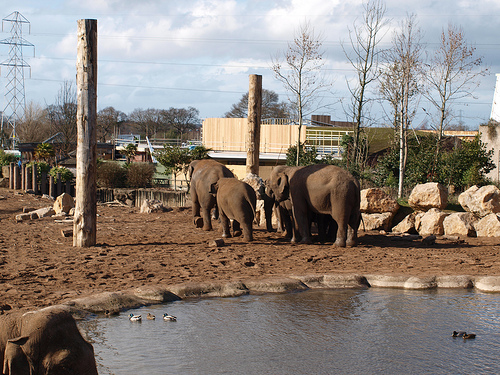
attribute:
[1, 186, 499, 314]
ground — sandy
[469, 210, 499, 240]
rock — big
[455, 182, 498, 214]
rock — big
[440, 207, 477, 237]
rock — big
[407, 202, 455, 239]
rock — big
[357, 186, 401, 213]
rock — big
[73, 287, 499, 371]
water — rippled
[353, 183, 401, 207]
rock — brown and gray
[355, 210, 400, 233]
rock — brown and gray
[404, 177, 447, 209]
rock — brown and gray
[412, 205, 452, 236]
rock — brown and gray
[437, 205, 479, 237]
rock — brown and gray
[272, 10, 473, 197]
trees — brown, dead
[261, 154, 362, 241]
elephant — brown, gray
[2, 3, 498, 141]
sky — cloudy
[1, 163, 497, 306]
ground — brown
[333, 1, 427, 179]
trees — dry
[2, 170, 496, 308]
dirt — brown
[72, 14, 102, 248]
pole — wooden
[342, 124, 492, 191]
bushes — green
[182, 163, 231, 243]
elephant — large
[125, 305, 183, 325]
ducks — three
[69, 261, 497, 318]
barrier — rock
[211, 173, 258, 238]
elephant — small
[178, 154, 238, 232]
elephant — bigger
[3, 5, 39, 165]
tower — tall, silver, electric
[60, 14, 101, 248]
post — tall, wooden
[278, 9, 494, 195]
trees — four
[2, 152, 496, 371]
area — enclosed